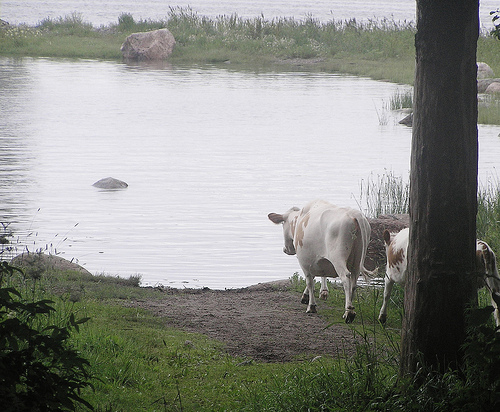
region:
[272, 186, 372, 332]
cow walking toward water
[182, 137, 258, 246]
light reflection on water surface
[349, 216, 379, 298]
tail on back of cow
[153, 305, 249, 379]
grass and dirt on ground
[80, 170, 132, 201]
top of rock in water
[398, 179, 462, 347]
bark on tree trunk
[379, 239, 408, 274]
brown fur on white cow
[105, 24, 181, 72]
rock on water's edge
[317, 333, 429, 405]
tall grass around tree base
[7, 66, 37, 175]
reflection on water surface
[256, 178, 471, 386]
the cow is white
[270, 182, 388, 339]
the cow is white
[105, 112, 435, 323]
the lake is clear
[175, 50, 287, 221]
the lake is clear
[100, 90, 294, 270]
the lake is clear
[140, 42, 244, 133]
the lake is clear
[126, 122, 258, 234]
the lake is clear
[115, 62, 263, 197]
the lake is clear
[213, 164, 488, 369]
two cows walking towards water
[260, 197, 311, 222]
ear of the cow pointing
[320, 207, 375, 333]
tail of the cow from behind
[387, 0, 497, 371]
large tree in foreground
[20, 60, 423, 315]
body of water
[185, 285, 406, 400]
dirt path leading to water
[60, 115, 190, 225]
rock sticking out of water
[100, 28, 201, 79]
boulder on side of lake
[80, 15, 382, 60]
green bushes growing by water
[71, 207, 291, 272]
ripples in the water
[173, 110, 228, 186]
this is a water body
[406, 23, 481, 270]
this is a tree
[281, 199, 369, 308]
this is a cow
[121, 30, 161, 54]
this is a rock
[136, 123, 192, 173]
the water is calm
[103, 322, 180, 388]
this is a grass area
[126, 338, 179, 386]
the grass is green in color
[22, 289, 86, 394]
the leaves are green in color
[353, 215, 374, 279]
this is the tail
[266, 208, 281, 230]
this is the ear